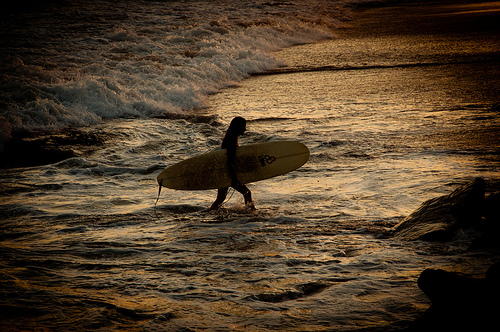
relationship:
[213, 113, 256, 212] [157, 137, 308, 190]
person was surfing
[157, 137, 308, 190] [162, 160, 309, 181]
surfboard has stringer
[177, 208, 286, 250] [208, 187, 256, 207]
water below knees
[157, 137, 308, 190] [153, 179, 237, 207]
surfboard has leash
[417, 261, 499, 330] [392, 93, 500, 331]
rocks on shoreline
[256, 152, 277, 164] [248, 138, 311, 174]
logo on board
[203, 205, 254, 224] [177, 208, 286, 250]
feet in water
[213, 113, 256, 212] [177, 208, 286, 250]
girl in water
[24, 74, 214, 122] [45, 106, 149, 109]
waves have bubbles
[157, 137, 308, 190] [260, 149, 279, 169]
board has design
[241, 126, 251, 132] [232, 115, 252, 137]
nose of profile